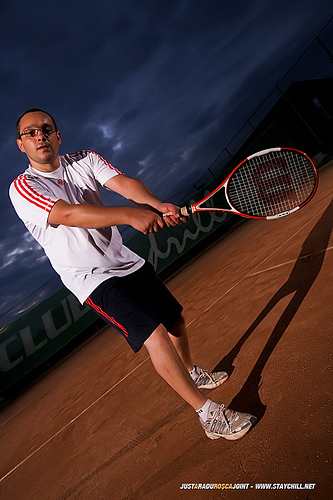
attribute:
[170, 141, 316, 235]
racket — big, round, white, red, black, long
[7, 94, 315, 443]
man — tall, posing, focused, white, red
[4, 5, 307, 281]
sky — blue, purple, black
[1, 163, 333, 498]
court — red, male, white, orange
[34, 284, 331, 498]
court — clay-based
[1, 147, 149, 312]
shirt — white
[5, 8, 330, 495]
day — stormy, cloudy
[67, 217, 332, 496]
tennis court — dirt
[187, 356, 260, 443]
shoes — Adidas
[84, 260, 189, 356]
shorts — navy blue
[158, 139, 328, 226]
tennis racket — red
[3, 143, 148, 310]
jersey — white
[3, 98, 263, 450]
tennis player — young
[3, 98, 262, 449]
male — young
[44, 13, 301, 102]
sky — overcast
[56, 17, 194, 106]
skies — gray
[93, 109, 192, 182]
clouds — white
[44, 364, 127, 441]
line — white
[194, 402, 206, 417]
lines — small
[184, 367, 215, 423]
socks — white